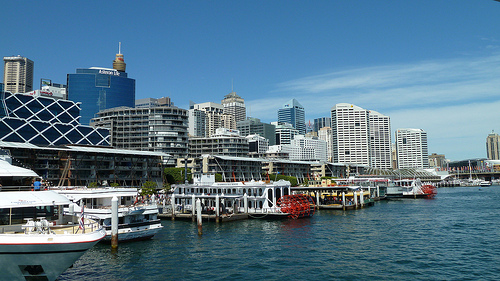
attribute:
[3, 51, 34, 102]
building — tall, brown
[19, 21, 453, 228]
building — tall, blue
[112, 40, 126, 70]
tower — radio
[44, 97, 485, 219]
harbor — urban